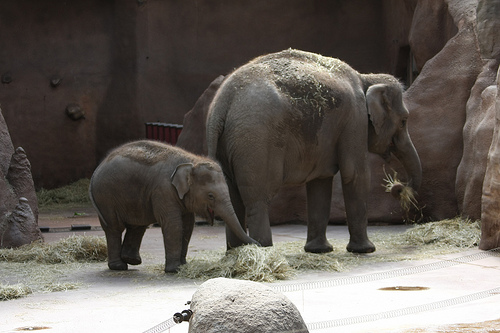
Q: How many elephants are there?
A: Two.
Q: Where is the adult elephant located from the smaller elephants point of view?
A: To the left.